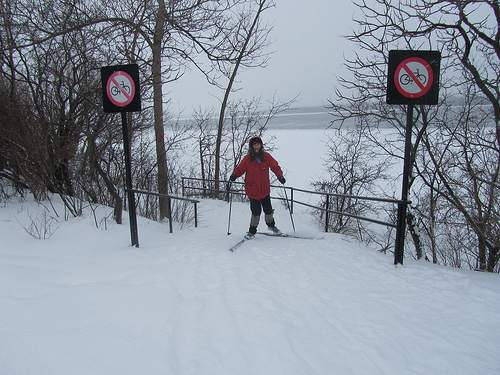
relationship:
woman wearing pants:
[219, 132, 282, 239] [241, 193, 273, 224]